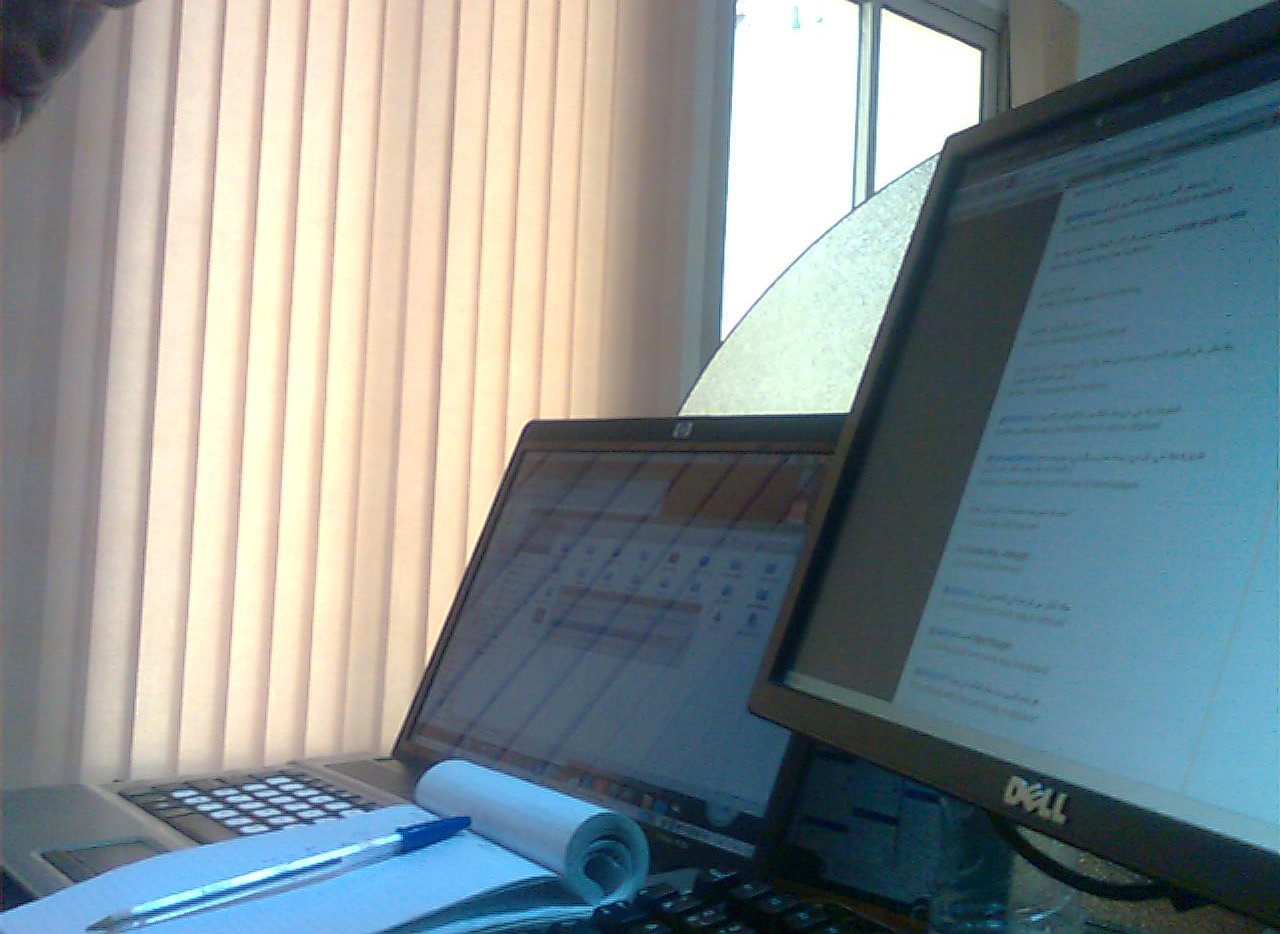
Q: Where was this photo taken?
A: At a computer desk.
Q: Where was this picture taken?
A: An office.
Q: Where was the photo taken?
A: Office.